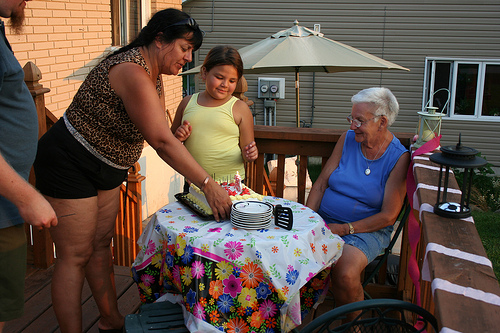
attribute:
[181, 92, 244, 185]
shirt — yellow, cheetah pattern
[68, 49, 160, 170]
shirt — leopard print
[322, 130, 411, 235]
shirt — blue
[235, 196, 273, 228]
plate — white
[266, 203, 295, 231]
spatulla — black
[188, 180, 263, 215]
cake — yellow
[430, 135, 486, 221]
lantern — black, green, sitting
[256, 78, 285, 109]
meter — silver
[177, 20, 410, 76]
umbrella — tan, cream, sitting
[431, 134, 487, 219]
candle holder — black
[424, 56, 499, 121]
window — white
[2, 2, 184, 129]
house — brick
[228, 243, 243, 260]
flower — pink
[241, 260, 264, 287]
flower — orange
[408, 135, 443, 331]
streamer — pink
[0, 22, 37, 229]
shirt — grey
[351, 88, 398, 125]
hair — white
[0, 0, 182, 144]
wall — brick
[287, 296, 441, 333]
chair — metal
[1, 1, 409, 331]
people — celebrating